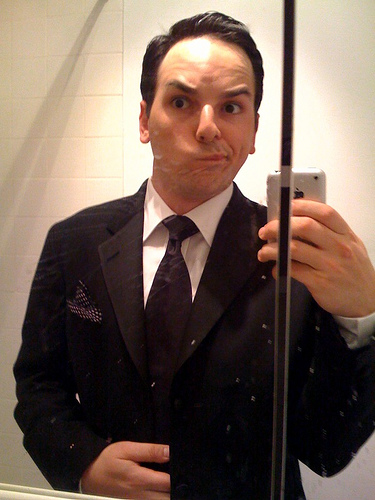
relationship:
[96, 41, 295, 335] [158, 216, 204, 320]
man wearing tie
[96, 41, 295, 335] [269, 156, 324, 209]
man holding phone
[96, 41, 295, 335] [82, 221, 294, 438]
man in suit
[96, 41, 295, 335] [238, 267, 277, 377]
man in mirror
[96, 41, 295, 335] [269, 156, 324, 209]
man with phone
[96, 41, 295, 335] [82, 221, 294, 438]
man with suit